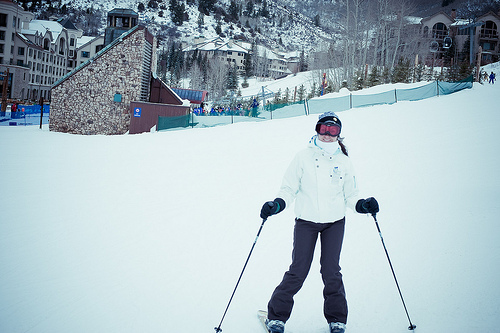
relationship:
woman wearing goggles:
[260, 110, 381, 332] [316, 118, 343, 138]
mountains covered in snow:
[1, 0, 500, 68] [0, 0, 498, 78]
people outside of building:
[195, 99, 262, 123] [169, 86, 209, 117]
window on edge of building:
[17, 46, 27, 56] [1, 1, 75, 107]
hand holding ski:
[356, 195, 380, 216] [367, 200, 419, 332]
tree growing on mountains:
[214, 20, 225, 37] [1, 0, 500, 68]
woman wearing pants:
[260, 110, 381, 332] [268, 217, 349, 325]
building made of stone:
[51, 25, 193, 136] [52, 25, 144, 132]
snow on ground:
[0, 0, 499, 332] [0, 61, 499, 331]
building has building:
[1, 1, 75, 107] [0, 0, 85, 101]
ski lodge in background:
[373, 0, 500, 77] [0, 1, 499, 133]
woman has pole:
[260, 110, 381, 332] [367, 200, 419, 332]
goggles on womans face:
[316, 118, 343, 138] [318, 118, 343, 143]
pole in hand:
[212, 202, 279, 331] [260, 200, 279, 220]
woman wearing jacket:
[260, 110, 381, 332] [274, 136, 367, 225]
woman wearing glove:
[260, 110, 381, 332] [356, 196, 381, 216]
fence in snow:
[154, 75, 473, 134] [0, 0, 499, 332]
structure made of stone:
[51, 25, 193, 136] [52, 25, 144, 132]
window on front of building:
[43, 37, 51, 53] [1, 1, 75, 107]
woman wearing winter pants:
[260, 110, 381, 332] [268, 217, 349, 325]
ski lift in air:
[443, 34, 453, 48] [2, 0, 500, 127]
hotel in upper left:
[1, 1, 75, 107] [0, 0, 108, 137]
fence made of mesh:
[154, 75, 473, 134] [164, 78, 474, 133]